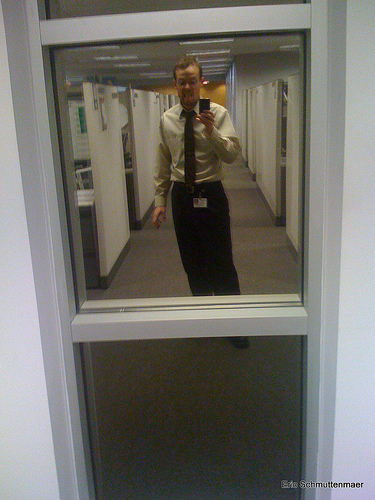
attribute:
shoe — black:
[171, 297, 289, 381]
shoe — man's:
[228, 337, 251, 348]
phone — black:
[192, 94, 225, 136]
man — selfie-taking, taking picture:
[150, 62, 240, 300]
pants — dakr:
[164, 178, 241, 299]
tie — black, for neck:
[175, 108, 207, 196]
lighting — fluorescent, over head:
[186, 49, 232, 53]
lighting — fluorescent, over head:
[175, 37, 237, 47]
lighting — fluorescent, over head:
[89, 55, 143, 65]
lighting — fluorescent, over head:
[115, 61, 153, 67]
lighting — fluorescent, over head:
[281, 45, 301, 50]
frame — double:
[22, 7, 337, 495]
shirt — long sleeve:
[155, 102, 240, 207]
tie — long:
[180, 108, 202, 206]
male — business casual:
[160, 57, 250, 346]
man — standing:
[160, 58, 244, 287]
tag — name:
[187, 192, 211, 209]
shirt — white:
[158, 94, 238, 181]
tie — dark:
[180, 108, 200, 199]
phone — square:
[194, 93, 208, 116]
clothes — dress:
[154, 103, 242, 289]